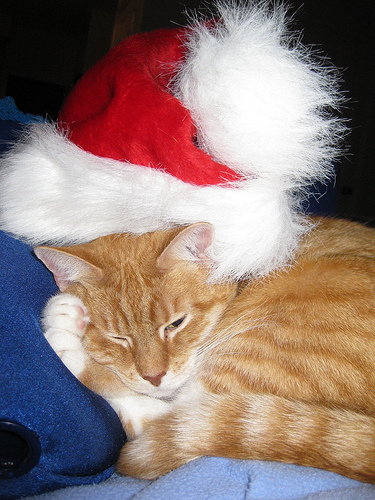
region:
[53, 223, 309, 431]
the cat is brown in colour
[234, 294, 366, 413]
it has white strippes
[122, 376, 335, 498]
its tail is near the face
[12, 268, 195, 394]
its paw is on the face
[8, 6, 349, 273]
white cotton is near its head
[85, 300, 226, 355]
its eyes are nearly closed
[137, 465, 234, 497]
the cloth is white in colour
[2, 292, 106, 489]
the seat is blue in colour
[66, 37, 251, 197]
a red ribbon on the cotton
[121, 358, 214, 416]
itsmouth is white in colour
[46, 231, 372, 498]
a orange cat laying down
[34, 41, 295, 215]
a red and white santa hat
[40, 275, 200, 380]
a cat with it's paw under it's head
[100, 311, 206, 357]
a cat with one eye closed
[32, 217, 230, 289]
a cats ears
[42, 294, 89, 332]
a cats front paw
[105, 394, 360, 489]
a orange cat's tail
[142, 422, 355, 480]
rings around a cat's tail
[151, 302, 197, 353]
a orange cat with a yellow eyes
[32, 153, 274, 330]
a cat with a santa hat on it's head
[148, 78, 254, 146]
A hat in the photo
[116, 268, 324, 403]
A cat in the photo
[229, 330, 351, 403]
Brown and white cat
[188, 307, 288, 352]
Whiskers of a cat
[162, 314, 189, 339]
Eye of a cat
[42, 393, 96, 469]
Blue pillows in the photo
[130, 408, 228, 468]
Tail of a cat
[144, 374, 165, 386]
Red nose of a cat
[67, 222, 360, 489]
A cat lying on the bed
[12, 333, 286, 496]
A bed in the photo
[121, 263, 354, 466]
this is a cat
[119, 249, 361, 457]
the cat is sleeping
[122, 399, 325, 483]
this is a tail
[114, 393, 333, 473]
the tail is long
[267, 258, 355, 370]
the fur is brown in color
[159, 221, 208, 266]
this is an ear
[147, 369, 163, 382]
this is the nose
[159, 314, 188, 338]
this is the eye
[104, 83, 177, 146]
this is a hat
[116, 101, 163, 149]
the hat is red in color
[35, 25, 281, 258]
big fluffy red and white hat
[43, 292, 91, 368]
white paws on a cat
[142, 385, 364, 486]
striped tail on a cat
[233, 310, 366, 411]
orange striped fur on a cat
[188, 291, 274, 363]
white whiskers on a cat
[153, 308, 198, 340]
open eye on a cat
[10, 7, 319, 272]
red and white santa hat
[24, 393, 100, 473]
blue colored pillow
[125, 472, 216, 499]
blue blanket with a cat on it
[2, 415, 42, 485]
dark circle on a blue pillow